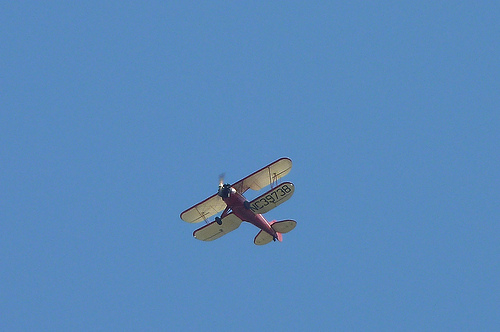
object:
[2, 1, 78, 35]
blue sky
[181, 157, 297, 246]
biplane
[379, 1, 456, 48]
sky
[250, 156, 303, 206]
wings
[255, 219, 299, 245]
tail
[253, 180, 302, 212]
wing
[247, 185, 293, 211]
number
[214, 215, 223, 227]
wheel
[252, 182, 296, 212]
letters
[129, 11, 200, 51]
sky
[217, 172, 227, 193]
propeller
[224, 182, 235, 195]
engine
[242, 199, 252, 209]
wheels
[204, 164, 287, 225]
rods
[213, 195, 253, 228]
landing gear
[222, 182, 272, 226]
body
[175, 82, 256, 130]
sky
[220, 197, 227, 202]
wheels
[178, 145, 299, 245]
wings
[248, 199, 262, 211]
nc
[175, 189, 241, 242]
white wings